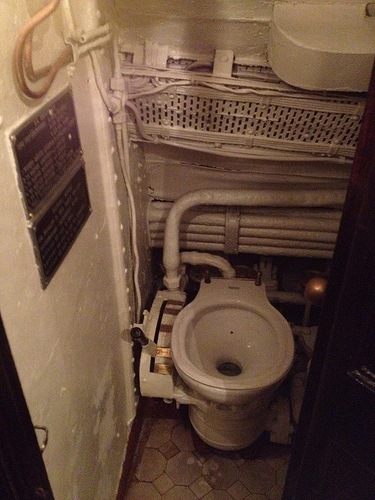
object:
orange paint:
[15, 27, 21, 73]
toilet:
[171, 276, 297, 453]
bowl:
[169, 277, 292, 390]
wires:
[128, 78, 293, 98]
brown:
[154, 468, 186, 491]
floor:
[124, 417, 291, 499]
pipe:
[113, 29, 119, 74]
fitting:
[107, 77, 127, 92]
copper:
[43, 121, 54, 158]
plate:
[152, 346, 175, 359]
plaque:
[9, 83, 82, 218]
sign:
[28, 155, 93, 290]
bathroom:
[0, 0, 374, 497]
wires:
[111, 116, 144, 324]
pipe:
[161, 187, 349, 292]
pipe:
[15, 0, 71, 97]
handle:
[129, 325, 157, 355]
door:
[279, 56, 375, 498]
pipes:
[149, 208, 341, 233]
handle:
[28, 420, 57, 453]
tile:
[132, 446, 166, 481]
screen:
[134, 91, 363, 149]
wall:
[0, 0, 158, 499]